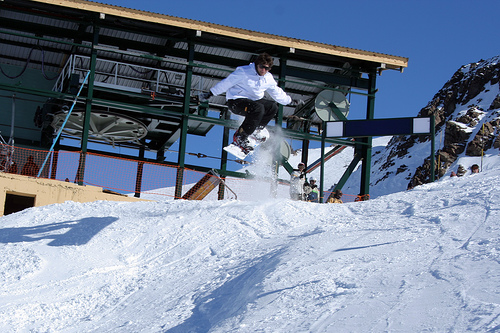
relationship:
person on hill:
[323, 187, 343, 201] [286, 132, 396, 204]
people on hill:
[306, 177, 318, 203] [286, 132, 396, 204]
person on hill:
[289, 162, 309, 197] [286, 132, 396, 204]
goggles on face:
[253, 61, 271, 68] [252, 57, 266, 74]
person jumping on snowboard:
[199, 46, 302, 167] [219, 123, 271, 163]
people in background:
[288, 158, 385, 211] [8, 12, 485, 209]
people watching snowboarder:
[288, 158, 385, 211] [194, 49, 309, 162]